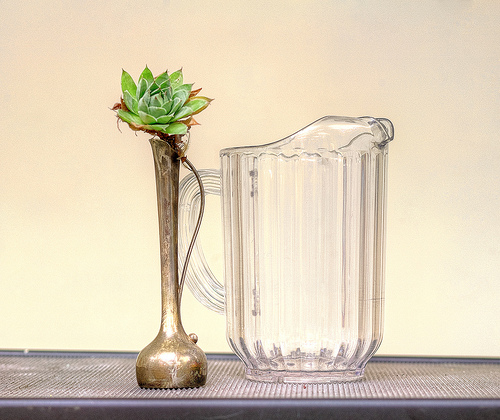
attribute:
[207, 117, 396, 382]
pitcher — empty, transparent, glass, clear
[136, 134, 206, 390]
vase — gold, long, metal, tarnished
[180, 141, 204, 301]
handle — thin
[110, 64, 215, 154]
flower — green, blooming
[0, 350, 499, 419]
table — silver, textured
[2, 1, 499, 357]
wall — beige, tan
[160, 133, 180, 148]
stem — red